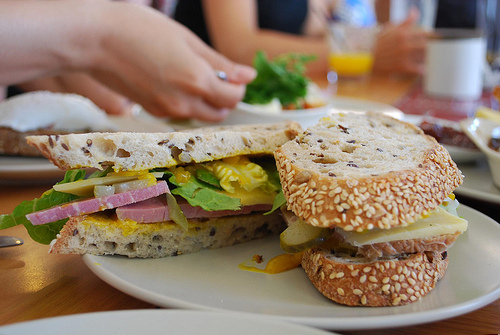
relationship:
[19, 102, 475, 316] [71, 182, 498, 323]
sandwich on plate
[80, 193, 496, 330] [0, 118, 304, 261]
plate with a sandwich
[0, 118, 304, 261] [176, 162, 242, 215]
sandwich with lettuce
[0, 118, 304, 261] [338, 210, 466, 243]
sandwich with cheese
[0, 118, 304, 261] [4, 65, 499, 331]
sandwich on a table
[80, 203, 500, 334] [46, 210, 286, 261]
plate with food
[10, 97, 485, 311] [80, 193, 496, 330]
food on a plate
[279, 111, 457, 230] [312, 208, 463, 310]
slice of bread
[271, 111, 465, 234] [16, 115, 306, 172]
slice of bread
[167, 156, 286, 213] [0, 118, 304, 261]
vegetables in sandwich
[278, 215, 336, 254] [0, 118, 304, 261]
vegetables in sandwich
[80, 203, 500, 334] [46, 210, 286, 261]
plate of food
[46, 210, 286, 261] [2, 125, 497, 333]
food on table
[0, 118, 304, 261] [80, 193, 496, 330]
sandwich on plate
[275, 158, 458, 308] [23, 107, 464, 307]
sesame seeds on bread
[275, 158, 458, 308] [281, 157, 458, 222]
sesame seeds on edge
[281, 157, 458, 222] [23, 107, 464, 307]
edge of bread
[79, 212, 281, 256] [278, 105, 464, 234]
mustard on bread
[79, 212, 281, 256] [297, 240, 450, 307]
mustard on bread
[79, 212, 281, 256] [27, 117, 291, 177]
mustard on bread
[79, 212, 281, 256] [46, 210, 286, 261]
mustard on food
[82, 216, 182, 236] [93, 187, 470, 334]
mustard on plate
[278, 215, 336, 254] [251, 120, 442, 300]
vegetables falling out of sandwich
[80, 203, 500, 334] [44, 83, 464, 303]
plate with sandwich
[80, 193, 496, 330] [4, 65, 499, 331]
plate on table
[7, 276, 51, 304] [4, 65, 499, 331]
part of table